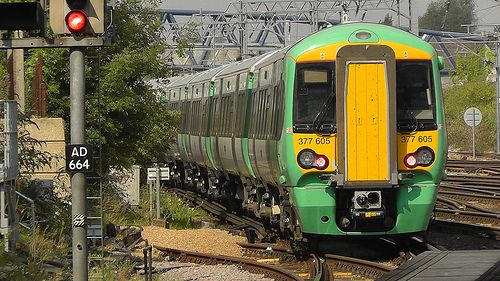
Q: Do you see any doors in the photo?
A: Yes, there is a door.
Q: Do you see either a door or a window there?
A: Yes, there is a door.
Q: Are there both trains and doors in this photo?
A: Yes, there are both a door and a train.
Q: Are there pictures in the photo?
A: No, there are no pictures.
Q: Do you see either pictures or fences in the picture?
A: No, there are no pictures or fences.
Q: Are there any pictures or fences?
A: No, there are no pictures or fences.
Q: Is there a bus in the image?
A: No, there are no buses.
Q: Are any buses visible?
A: No, there are no buses.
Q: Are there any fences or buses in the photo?
A: No, there are no buses or fences.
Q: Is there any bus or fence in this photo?
A: No, there are no buses or fences.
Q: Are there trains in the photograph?
A: Yes, there is a train.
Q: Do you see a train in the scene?
A: Yes, there is a train.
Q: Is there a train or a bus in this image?
A: Yes, there is a train.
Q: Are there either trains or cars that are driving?
A: Yes, the train is driving.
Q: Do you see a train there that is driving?
A: Yes, there is a train that is driving.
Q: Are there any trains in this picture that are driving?
A: Yes, there is a train that is driving.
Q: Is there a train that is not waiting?
A: Yes, there is a train that is driving.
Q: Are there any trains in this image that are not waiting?
A: Yes, there is a train that is driving.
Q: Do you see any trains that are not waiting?
A: Yes, there is a train that is driving .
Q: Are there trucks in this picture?
A: No, there are no trucks.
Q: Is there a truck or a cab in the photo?
A: No, there are no trucks or taxis.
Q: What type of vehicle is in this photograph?
A: The vehicle is a train.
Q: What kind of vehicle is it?
A: The vehicle is a train.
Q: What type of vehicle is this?
A: This is a train.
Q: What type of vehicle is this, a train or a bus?
A: This is a train.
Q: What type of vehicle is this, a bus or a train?
A: This is a train.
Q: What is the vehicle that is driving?
A: The vehicle is a train.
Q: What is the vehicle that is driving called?
A: The vehicle is a train.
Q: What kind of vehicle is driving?
A: The vehicle is a train.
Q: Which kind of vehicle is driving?
A: The vehicle is a train.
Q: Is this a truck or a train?
A: This is a train.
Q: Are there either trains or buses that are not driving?
A: No, there is a train but it is driving.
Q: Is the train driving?
A: Yes, the train is driving.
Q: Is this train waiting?
A: No, the train is driving.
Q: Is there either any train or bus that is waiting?
A: No, there is a train but it is driving.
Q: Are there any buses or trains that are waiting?
A: No, there is a train but it is driving.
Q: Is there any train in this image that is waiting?
A: No, there is a train but it is driving.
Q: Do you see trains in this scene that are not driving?
A: No, there is a train but it is driving.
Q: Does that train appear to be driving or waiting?
A: The train is driving.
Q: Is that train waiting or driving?
A: The train is driving.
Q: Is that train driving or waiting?
A: The train is driving.